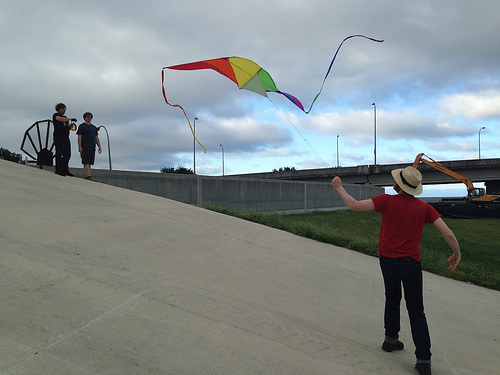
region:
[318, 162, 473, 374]
Man wearing red shirt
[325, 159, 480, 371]
Man wearing white hat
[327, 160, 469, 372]
Man wearing black pants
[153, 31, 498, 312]
Man flying rainbow colored kite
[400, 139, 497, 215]
Orange construction crane under bridge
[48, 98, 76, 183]
Man wearing black shirt and pants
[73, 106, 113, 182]
Man wearing black shirt and black shorts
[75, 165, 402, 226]
Long wooden fence in park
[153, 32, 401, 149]
Flying rainbow colored kite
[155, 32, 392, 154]
Rainbow colored kite in front of clouds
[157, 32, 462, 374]
a person flying a kite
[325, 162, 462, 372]
a person in red shirt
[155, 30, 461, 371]
a person in red flying a kite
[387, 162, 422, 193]
a hat the person is wearing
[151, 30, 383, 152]
a kite the person is flying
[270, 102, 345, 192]
a string of the kite the person is holding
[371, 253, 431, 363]
dark pants the person is wearing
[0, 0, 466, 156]
clouds in the sky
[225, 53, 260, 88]
a triangular yellow part of the kite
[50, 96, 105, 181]
two people standing in the background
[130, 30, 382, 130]
an object in air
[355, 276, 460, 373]
legs of the person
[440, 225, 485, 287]
hand of the person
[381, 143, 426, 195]
cap wearing by person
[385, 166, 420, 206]
white cap on head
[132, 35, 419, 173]
a kite flying in air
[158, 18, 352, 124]
a colorful kite in air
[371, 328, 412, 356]
shoe of the person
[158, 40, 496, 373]
a boy holding kite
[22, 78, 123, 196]
two people standing on top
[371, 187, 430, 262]
the shirt is red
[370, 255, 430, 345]
the pants are black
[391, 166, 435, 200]
the hat is white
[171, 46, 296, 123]
the kite is in the air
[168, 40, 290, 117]
the kite is red yellow and green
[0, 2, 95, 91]
clouds are in the sky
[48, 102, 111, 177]
two people are on top of the slope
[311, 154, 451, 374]
the man is holding rope of the kite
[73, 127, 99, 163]
the clothes are black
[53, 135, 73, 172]
the pantsa re black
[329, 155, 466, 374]
man with beige straw hat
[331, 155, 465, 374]
man wearing red shirt and black pants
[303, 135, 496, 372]
man holding kite string with crane in background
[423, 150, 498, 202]
yellow crane working alongside highway bridge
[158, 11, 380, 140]
multi-colored kite flowing in the wind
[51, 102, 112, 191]
two adults standing on sloped pavement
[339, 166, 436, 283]
man in red shirt standing in front of grassy yard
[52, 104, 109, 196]
two adults wearing dark colored clothing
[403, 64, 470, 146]
scene of cloudy sky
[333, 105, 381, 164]
two tall lamp posts standing amongst cloudy sky